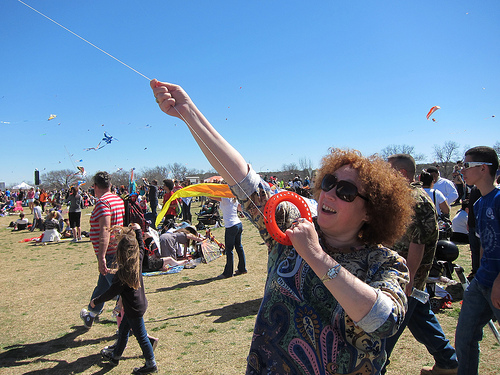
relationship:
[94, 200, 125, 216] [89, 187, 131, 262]
stripe on shirt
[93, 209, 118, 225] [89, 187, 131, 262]
stripe on shirt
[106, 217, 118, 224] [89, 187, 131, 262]
stripe on shirt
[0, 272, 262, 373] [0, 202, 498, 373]
shadows on ground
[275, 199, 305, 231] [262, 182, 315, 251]
hole in ring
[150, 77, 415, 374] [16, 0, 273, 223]
kite flyer holding kite string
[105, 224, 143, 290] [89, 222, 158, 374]
hair on child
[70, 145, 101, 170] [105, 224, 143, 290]
wind blowing hair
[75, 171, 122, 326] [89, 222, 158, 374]
father holding hands with child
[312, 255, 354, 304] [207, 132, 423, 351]
watch on wrist of kite flyer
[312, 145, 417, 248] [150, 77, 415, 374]
hair part of kite flyer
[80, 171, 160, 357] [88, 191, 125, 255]
father wearing shirt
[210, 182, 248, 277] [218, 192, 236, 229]
girl wearing shirt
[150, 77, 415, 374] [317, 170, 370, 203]
kite flyer wears sunglasses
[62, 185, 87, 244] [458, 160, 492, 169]
people wears sunglasses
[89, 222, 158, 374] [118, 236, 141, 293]
child has hair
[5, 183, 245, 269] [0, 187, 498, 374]
people in field